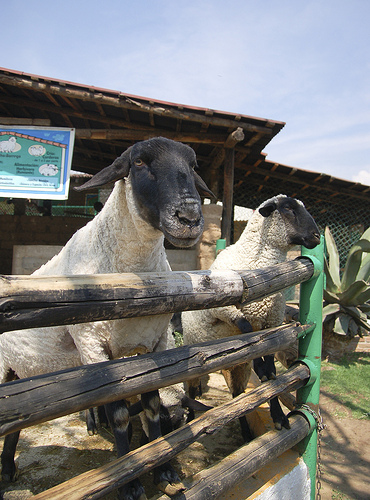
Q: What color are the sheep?
A: Beige.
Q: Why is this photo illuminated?
A: Sunlight.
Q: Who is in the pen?
A: The sheep.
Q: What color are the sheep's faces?
A: Black.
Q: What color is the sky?
A: Blue.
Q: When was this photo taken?
A: During the day.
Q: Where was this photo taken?
A: At a farm.